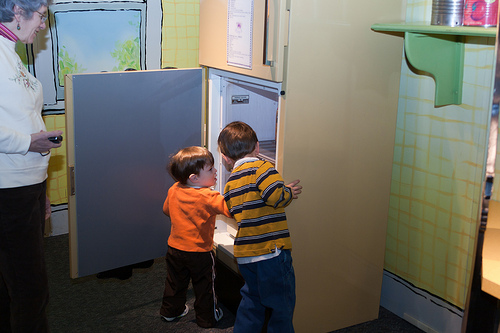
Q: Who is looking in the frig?
A: The kids.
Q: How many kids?
A: 2.